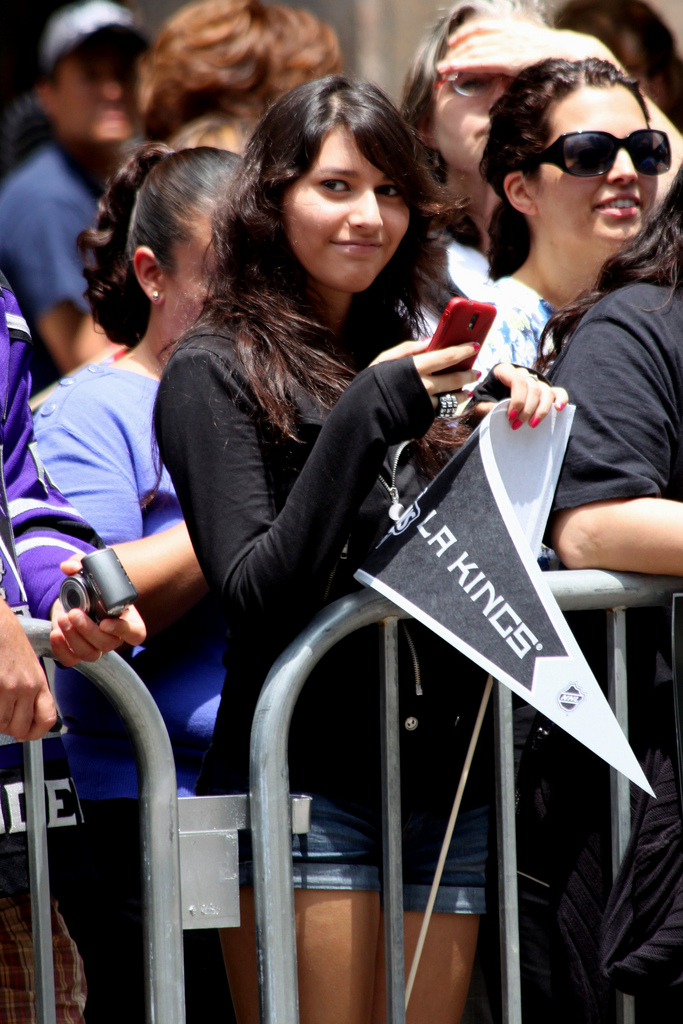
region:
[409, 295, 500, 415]
Red cell phone with camera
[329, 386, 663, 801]
Black and white LA Kings banner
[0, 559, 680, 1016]
Silver gate with door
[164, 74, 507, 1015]
Woman wearing a black shirt and shorts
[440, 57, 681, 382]
Woman wearing sun glasses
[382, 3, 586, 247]
Woman wearing regular glasses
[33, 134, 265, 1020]
Woman with pony tail and purple shirt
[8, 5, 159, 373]
Man in blue wearing a hat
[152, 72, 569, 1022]
woman wearing blue shorts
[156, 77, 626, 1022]
woman wearing a black shirt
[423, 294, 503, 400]
a small red cell phone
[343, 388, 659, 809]
black and white flag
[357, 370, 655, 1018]
black and white flag on a stick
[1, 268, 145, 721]
person in a purple shirt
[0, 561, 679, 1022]
a silver metal fence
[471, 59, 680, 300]
woman wearing black sunglasses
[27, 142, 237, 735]
woman wearing purple shirt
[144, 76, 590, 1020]
woman holding a cell phone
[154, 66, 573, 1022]
the girl holding a phone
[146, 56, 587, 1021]
the girl holding a banner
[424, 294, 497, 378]
the phone is red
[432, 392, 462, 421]
the ring on the finger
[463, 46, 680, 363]
girl wearing sunglasses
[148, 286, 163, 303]
the earring in the ear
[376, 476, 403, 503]
the zipper on the shirt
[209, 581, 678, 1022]
the barricade is metal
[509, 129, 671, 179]
the glasses are black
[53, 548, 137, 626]
the camera is gray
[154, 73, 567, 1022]
the girl is holding a phone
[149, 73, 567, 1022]
the girl is wearing a ring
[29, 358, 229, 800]
the shirt is purple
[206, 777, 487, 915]
the shorts are blue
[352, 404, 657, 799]
the triangle flag is black and white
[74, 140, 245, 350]
the hair is pulled in a ponytail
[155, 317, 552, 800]
the jacket is black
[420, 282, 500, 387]
Red phone on girl's hand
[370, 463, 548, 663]
Team name on a banner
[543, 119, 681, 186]
Sunglasses on a woman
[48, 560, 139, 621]
Camera in person's hand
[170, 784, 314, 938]
Latch on a gate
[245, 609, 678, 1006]
Gate made of metal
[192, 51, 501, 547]
Girl holding a phone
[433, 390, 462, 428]
Large ring on finger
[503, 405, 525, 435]
Nails that are painted pink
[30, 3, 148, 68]
Hat on a man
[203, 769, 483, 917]
the shorts are blue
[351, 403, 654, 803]
the triangle flag is black and white